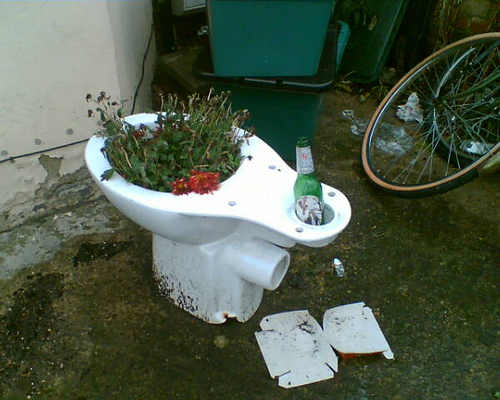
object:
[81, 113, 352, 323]
toilet bowl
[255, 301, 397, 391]
trash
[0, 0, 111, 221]
paint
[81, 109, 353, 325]
toilet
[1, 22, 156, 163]
wires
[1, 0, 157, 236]
wall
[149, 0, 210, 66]
space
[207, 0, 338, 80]
containers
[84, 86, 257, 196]
plant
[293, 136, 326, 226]
alcohol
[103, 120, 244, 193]
bowl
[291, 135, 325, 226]
beer bottle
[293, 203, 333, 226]
toilet hole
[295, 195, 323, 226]
labels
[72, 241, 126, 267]
hole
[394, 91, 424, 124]
trash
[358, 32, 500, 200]
bike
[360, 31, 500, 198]
bike tire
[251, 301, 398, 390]
party cups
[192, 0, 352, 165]
bins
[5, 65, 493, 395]
yard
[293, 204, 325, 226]
beer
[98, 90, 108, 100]
flower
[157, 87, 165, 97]
flower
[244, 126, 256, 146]
flower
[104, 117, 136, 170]
stem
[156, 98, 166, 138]
stem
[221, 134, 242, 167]
stem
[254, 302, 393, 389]
container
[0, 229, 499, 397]
ground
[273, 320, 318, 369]
inside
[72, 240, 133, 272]
shape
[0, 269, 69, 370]
shape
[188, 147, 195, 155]
flower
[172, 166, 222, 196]
flower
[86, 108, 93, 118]
flower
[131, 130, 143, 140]
flower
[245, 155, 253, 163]
flower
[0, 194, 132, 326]
base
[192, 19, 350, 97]
lid